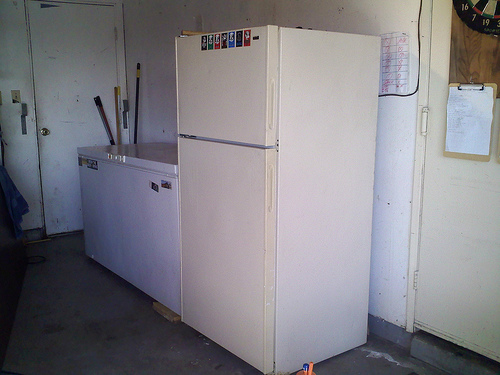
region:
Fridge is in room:
[167, 23, 379, 374]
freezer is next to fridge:
[74, 138, 185, 314]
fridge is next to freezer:
[172, 26, 372, 373]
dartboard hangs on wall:
[451, 0, 499, 37]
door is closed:
[24, 0, 146, 237]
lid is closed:
[76, 141, 182, 177]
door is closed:
[174, 24, 277, 373]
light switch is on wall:
[9, 88, 23, 105]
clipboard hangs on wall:
[440, 81, 493, 161]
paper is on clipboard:
[444, 85, 493, 157]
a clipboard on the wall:
[442, 80, 495, 164]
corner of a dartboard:
[453, 1, 498, 43]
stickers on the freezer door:
[198, 29, 252, 51]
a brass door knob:
[41, 126, 51, 137]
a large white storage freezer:
[76, 142, 183, 316]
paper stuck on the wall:
[380, 30, 409, 94]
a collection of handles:
[95, 62, 140, 144]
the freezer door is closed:
[174, 26, 276, 146]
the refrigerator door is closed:
[168, 145, 275, 373]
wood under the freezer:
[152, 298, 180, 322]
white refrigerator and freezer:
[169, 22, 383, 374]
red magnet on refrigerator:
[244, 29, 251, 46]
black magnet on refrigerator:
[234, 30, 241, 50]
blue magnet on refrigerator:
[229, 32, 236, 49]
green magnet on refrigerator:
[206, 35, 213, 50]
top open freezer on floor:
[77, 139, 183, 321]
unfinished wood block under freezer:
[148, 301, 180, 328]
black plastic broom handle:
[132, 61, 142, 144]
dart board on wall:
[454, 1, 499, 39]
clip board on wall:
[445, 82, 496, 164]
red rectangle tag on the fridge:
[241, 27, 252, 48]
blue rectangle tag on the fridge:
[226, 28, 236, 49]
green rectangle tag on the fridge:
[205, 32, 214, 51]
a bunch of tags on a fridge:
[194, 27, 255, 53]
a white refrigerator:
[170, 24, 377, 371]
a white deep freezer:
[68, 132, 184, 322]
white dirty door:
[20, 0, 130, 240]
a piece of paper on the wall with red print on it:
[376, 29, 414, 96]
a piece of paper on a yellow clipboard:
[439, 77, 496, 165]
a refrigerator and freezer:
[22, 6, 440, 315]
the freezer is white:
[87, 24, 187, 295]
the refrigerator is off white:
[172, 25, 381, 373]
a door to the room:
[408, 17, 499, 352]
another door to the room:
[9, 11, 76, 263]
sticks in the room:
[85, 47, 165, 147]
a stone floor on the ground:
[10, 224, 247, 374]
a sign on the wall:
[363, 19, 420, 100]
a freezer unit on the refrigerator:
[149, 29, 309, 143]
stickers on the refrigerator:
[183, 19, 265, 59]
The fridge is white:
[150, 13, 392, 373]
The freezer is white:
[61, 111, 212, 321]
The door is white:
[17, 5, 156, 270]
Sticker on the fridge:
[230, 20, 312, 184]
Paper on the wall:
[365, 10, 440, 266]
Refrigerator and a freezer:
[76, 20, 381, 373]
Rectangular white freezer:
[76, 138, 183, 318]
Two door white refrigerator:
[172, 21, 386, 370]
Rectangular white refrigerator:
[171, 20, 383, 368]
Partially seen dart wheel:
[451, 0, 499, 36]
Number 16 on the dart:
[450, 0, 498, 37]